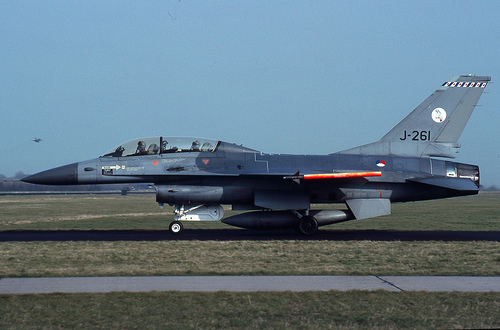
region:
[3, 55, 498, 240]
A jet in the foreground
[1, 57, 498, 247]
A side view of a jet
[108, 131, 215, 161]
People are inside a jet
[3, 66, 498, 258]
The jet is on the ground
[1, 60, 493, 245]
The jet is dark gray in color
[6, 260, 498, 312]
A sidewalk in the foreground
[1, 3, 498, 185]
The sky is clear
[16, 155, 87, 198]
The nose of the jet is gunmetal gray in color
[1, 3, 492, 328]
Photo was taken in the daytime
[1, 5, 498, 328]
Photo was taken outdoors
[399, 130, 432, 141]
jet number is written in black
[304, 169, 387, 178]
red tip of the wing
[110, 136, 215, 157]
clear windshield on the plane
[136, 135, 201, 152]
two pilots in the plane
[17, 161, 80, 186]
nose of the jet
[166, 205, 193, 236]
landing gear wheel is down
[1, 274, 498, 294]
a concrete sidewalk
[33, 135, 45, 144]
a plane in the distance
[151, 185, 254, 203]
engine on the wing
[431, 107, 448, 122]
white circle on the tail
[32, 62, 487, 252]
picture of military jet fighter plane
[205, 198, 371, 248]
missle attached to bottom of the plane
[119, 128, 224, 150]
two pilots in the plane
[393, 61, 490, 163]
tail of place with J-261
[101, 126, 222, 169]
clear plastic over pilots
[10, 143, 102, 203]
pointy nose of jet fighter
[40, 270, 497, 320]
sidewalk between to grassy areas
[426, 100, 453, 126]
round white sticker on tail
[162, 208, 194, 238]
black and white wheels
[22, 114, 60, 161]
airplane in the sky in the distance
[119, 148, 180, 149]
Black and silver plane on the ground.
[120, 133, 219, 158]
two pilots in jet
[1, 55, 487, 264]
grey fet fighter plane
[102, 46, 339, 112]
sky with no clouds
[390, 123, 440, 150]
black letters and numbers on tail of plane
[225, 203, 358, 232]
missle attached to bottom of the plane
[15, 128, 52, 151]
airplance in the sky in the distance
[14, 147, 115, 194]
pointy nose of jet fighter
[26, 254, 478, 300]
sidewalk near runway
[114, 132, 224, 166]
clear plastic above jet fighter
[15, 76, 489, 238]
large long metal jet plane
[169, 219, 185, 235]
small round black wheel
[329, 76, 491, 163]
large metal grey jet tail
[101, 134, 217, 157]
large glass jet window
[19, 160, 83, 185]
pointy metal dark nose of jet